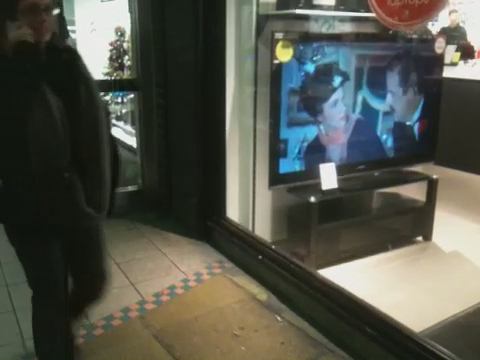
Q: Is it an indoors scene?
A: Yes, it is indoors.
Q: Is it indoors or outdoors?
A: It is indoors.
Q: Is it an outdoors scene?
A: No, it is indoors.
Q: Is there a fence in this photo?
A: No, there are no fences.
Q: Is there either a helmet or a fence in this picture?
A: No, there are no fences or helmets.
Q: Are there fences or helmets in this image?
A: No, there are no fences or helmets.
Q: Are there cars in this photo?
A: No, there are no cars.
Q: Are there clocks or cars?
A: No, there are no cars or clocks.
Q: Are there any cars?
A: No, there are no cars.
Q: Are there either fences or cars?
A: No, there are no cars or fences.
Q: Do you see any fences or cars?
A: No, there are no cars or fences.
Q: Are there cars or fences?
A: No, there are no cars or fences.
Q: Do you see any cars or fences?
A: No, there are no cars or fences.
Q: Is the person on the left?
A: Yes, the person is on the left of the image.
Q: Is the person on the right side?
A: No, the person is on the left of the image.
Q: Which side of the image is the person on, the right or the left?
A: The person is on the left of the image.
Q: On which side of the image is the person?
A: The person is on the left of the image.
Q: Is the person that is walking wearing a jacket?
A: Yes, the person is wearing a jacket.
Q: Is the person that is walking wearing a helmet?
A: No, the person is wearing a jacket.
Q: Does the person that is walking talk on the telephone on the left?
A: Yes, the person talks on the telephone.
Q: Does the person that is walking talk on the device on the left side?
A: Yes, the person talks on the telephone.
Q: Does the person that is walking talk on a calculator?
A: No, the person talks on the telephone.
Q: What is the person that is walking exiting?
A: The person is exiting the store.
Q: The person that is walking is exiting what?
A: The person is exiting the store.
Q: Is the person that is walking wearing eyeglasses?
A: Yes, the person is wearing eyeglasses.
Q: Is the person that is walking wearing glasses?
A: No, the person is wearing eyeglasses.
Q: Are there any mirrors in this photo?
A: No, there are no mirrors.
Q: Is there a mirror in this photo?
A: No, there are no mirrors.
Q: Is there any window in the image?
A: Yes, there is a window.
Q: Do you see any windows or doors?
A: Yes, there is a window.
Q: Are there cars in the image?
A: No, there are no cars.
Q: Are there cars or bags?
A: No, there are no cars or bags.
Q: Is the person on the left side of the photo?
A: Yes, the person is on the left of the image.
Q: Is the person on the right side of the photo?
A: No, the person is on the left of the image.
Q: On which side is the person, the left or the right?
A: The person is on the left of the image.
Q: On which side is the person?
A: The person is on the left of the image.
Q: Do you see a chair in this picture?
A: No, there are no chairs.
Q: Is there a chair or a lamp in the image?
A: No, there are no chairs or lamps.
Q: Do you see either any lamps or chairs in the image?
A: No, there are no chairs or lamps.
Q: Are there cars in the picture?
A: No, there are no cars.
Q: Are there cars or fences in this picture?
A: No, there are no cars or fences.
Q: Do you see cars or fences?
A: No, there are no cars or fences.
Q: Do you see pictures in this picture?
A: No, there are no pictures.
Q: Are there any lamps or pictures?
A: No, there are no pictures or lamps.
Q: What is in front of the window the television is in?
A: The floor is in front of the window.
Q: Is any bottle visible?
A: No, there are no bottles.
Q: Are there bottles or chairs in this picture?
A: No, there are no bottles or chairs.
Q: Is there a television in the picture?
A: Yes, there is a television.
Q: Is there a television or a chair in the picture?
A: Yes, there is a television.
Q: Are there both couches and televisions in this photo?
A: No, there is a television but no couches.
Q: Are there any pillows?
A: No, there are no pillows.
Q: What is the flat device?
A: The device is a television.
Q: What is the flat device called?
A: The device is a television.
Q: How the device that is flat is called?
A: The device is a television.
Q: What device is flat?
A: The device is a television.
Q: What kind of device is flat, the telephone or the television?
A: The television is flat.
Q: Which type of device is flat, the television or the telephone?
A: The television is flat.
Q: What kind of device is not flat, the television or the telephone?
A: The telephone is not flat.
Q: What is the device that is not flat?
A: The device is a phone.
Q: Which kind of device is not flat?
A: The device is a phone.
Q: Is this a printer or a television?
A: This is a television.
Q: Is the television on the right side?
A: Yes, the television is on the right of the image.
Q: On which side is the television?
A: The television is on the right of the image.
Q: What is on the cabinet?
A: The TV is on the cabinet.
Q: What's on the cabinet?
A: The TV is on the cabinet.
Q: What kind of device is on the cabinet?
A: The device is a television.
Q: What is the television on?
A: The television is on the cabinet.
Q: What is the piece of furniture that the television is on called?
A: The piece of furniture is a cabinet.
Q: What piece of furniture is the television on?
A: The television is on the cabinet.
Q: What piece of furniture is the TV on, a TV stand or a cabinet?
A: The TV is on a cabinet.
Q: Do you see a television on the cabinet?
A: Yes, there is a television on the cabinet.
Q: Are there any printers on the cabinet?
A: No, there is a television on the cabinet.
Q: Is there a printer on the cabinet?
A: No, there is a television on the cabinet.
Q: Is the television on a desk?
A: No, the television is on the cabinet.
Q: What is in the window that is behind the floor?
A: The television is in the window.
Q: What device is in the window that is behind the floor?
A: The device is a television.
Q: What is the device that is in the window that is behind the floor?
A: The device is a television.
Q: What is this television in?
A: The television is in the window.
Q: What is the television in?
A: The television is in the window.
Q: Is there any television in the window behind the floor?
A: Yes, there is a television in the window.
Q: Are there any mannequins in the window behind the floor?
A: No, there is a television in the window.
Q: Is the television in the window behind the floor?
A: Yes, the television is in the window.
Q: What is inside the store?
A: The TV is inside the store.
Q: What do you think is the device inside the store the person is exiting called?
A: The device is a television.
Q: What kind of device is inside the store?
A: The device is a television.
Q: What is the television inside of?
A: The television is inside the store.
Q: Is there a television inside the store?
A: Yes, there is a television inside the store.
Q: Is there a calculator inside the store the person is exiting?
A: No, there is a television inside the store.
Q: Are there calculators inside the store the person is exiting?
A: No, there is a television inside the store.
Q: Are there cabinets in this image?
A: Yes, there is a cabinet.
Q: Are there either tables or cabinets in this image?
A: Yes, there is a cabinet.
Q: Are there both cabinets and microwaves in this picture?
A: No, there is a cabinet but no microwaves.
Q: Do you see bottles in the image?
A: No, there are no bottles.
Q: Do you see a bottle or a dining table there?
A: No, there are no bottles or dining tables.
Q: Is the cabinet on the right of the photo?
A: Yes, the cabinet is on the right of the image.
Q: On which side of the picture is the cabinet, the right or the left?
A: The cabinet is on the right of the image.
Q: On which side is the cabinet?
A: The cabinet is on the right of the image.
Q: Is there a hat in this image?
A: Yes, there is a hat.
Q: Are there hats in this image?
A: Yes, there is a hat.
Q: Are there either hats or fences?
A: Yes, there is a hat.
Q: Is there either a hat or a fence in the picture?
A: Yes, there is a hat.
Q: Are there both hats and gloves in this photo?
A: No, there is a hat but no gloves.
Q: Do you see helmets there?
A: No, there are no helmets.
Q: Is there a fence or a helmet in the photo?
A: No, there are no helmets or fences.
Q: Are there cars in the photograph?
A: No, there are no cars.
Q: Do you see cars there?
A: No, there are no cars.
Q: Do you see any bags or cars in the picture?
A: No, there are no cars or bags.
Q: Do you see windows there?
A: Yes, there is a window.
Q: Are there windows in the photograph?
A: Yes, there is a window.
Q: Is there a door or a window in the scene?
A: Yes, there is a window.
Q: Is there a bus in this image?
A: No, there are no buses.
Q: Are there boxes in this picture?
A: No, there are no boxes.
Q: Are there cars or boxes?
A: No, there are no boxes or cars.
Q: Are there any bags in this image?
A: No, there are no bags.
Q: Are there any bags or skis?
A: No, there are no bags or skis.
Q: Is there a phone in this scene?
A: Yes, there is a phone.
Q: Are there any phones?
A: Yes, there is a phone.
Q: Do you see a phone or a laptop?
A: Yes, there is a phone.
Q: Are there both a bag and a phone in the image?
A: No, there is a phone but no bags.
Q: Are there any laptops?
A: No, there are no laptops.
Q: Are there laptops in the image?
A: No, there are no laptops.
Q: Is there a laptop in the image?
A: No, there are no laptops.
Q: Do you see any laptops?
A: No, there are no laptops.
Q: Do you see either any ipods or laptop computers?
A: No, there are no laptop computers or ipods.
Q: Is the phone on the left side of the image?
A: Yes, the phone is on the left of the image.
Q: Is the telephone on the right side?
A: No, the telephone is on the left of the image.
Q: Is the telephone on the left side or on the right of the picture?
A: The telephone is on the left of the image.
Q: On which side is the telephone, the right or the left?
A: The telephone is on the left of the image.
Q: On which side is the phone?
A: The phone is on the left of the image.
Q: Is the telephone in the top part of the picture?
A: Yes, the telephone is in the top of the image.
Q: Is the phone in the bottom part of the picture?
A: No, the phone is in the top of the image.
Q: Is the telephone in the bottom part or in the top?
A: The telephone is in the top of the image.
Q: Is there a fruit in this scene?
A: No, there are no fruits.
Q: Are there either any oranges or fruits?
A: No, there are no fruits or oranges.